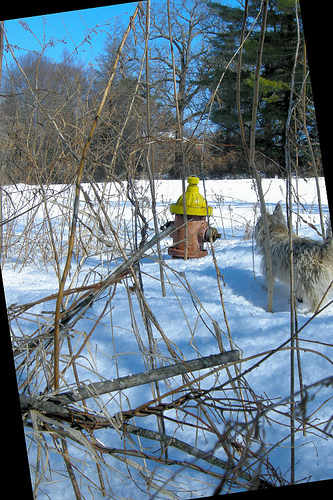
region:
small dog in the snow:
[229, 197, 332, 340]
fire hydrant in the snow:
[145, 150, 218, 285]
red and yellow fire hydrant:
[140, 156, 223, 306]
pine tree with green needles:
[204, 0, 316, 187]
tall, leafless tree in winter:
[118, 5, 208, 182]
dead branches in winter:
[24, 328, 327, 475]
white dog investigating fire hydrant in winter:
[157, 161, 332, 318]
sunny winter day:
[12, 23, 120, 227]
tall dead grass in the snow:
[3, 220, 60, 285]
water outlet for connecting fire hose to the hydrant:
[192, 218, 225, 250]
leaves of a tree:
[273, 83, 278, 89]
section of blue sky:
[95, 10, 106, 16]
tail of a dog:
[326, 236, 328, 248]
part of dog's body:
[300, 244, 307, 252]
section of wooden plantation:
[37, 127, 97, 185]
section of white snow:
[229, 185, 242, 192]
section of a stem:
[267, 99, 273, 127]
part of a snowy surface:
[316, 450, 324, 462]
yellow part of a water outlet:
[195, 194, 202, 202]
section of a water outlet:
[192, 219, 199, 238]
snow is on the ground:
[29, 167, 332, 477]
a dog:
[247, 204, 331, 330]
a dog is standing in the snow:
[251, 202, 331, 336]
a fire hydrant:
[164, 168, 222, 280]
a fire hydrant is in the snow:
[163, 163, 232, 278]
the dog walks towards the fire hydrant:
[162, 167, 330, 336]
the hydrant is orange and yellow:
[155, 170, 223, 283]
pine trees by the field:
[191, 8, 332, 176]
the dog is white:
[251, 202, 331, 321]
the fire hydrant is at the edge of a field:
[25, 167, 326, 258]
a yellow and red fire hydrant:
[155, 169, 221, 280]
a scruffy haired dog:
[243, 200, 323, 322]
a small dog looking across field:
[225, 197, 313, 320]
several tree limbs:
[11, 363, 252, 446]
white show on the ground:
[0, 249, 253, 364]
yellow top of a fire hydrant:
[164, 174, 208, 216]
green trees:
[184, 103, 270, 141]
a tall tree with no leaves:
[132, 0, 214, 131]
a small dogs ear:
[244, 192, 293, 252]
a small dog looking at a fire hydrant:
[95, 178, 326, 319]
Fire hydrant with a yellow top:
[146, 164, 228, 231]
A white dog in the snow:
[244, 201, 319, 313]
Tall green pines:
[205, 3, 300, 147]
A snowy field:
[60, 164, 312, 209]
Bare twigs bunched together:
[35, 303, 255, 458]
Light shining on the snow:
[224, 172, 276, 198]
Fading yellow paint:
[173, 184, 205, 207]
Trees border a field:
[28, 70, 265, 180]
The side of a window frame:
[3, 361, 86, 488]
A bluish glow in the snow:
[126, 263, 287, 359]